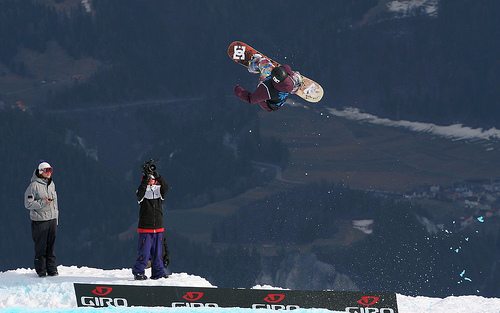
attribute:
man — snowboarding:
[220, 51, 305, 118]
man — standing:
[125, 156, 177, 283]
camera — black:
[139, 157, 161, 180]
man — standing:
[21, 157, 62, 278]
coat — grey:
[21, 166, 63, 225]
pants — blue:
[129, 229, 174, 281]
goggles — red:
[38, 160, 58, 175]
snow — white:
[1, 262, 493, 311]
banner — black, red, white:
[70, 280, 404, 311]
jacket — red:
[233, 65, 299, 110]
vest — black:
[259, 78, 295, 114]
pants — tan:
[245, 56, 279, 80]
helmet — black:
[269, 64, 291, 87]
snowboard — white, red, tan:
[222, 37, 327, 104]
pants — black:
[26, 214, 62, 279]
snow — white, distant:
[324, 97, 499, 152]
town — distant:
[400, 172, 499, 220]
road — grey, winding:
[20, 85, 228, 110]